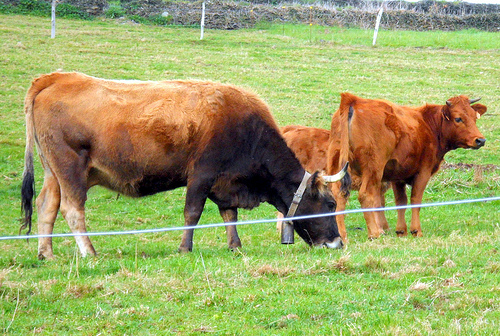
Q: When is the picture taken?
A: Daytime.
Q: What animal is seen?
A: Cow.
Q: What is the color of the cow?
A: Brown.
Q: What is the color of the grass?
A: Green.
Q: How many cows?
A: 3.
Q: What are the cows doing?
A: Eating.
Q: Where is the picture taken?
A: On the farm.